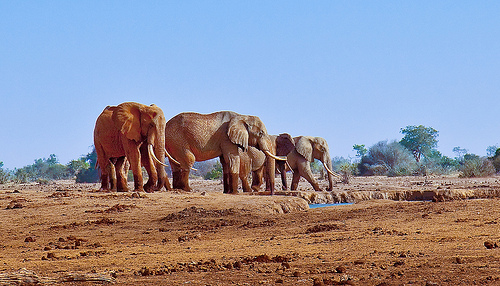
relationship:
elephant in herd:
[93, 102, 179, 192] [93, 100, 342, 197]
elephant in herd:
[165, 111, 287, 196] [93, 100, 342, 197]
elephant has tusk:
[93, 102, 197, 193] [148, 141, 165, 167]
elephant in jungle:
[165, 111, 287, 196] [3, 68, 482, 242]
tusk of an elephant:
[145, 142, 199, 171] [93, 102, 179, 192]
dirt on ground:
[131, 181, 363, 273] [2, 171, 484, 283]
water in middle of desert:
[309, 197, 354, 208] [1, 169, 480, 282]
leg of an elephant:
[125, 149, 149, 195] [94, 101, 168, 192]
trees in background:
[338, 122, 491, 167] [3, 22, 482, 185]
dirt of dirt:
[162, 200, 238, 226] [95, 189, 279, 249]